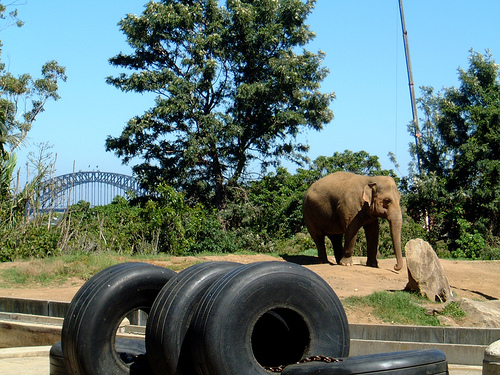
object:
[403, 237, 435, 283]
stump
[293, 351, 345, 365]
chain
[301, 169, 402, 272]
elephant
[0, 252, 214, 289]
grass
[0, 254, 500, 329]
dirt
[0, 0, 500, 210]
sky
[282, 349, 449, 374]
tire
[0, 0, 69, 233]
tree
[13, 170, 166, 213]
bridge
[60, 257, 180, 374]
tires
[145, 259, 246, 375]
tires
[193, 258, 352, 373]
tires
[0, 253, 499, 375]
ground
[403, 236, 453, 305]
rock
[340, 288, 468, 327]
grass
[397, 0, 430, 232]
pole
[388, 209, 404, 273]
trunk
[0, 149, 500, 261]
bushes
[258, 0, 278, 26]
leaves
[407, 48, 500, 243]
tree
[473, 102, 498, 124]
leaves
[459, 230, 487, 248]
leaves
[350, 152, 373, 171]
leaves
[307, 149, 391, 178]
tree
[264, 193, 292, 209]
leaves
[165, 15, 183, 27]
leaves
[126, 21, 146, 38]
leaves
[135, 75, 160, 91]
leaves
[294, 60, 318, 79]
leaves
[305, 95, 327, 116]
leaves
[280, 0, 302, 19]
leaves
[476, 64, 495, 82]
leaves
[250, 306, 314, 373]
hole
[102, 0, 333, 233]
tree